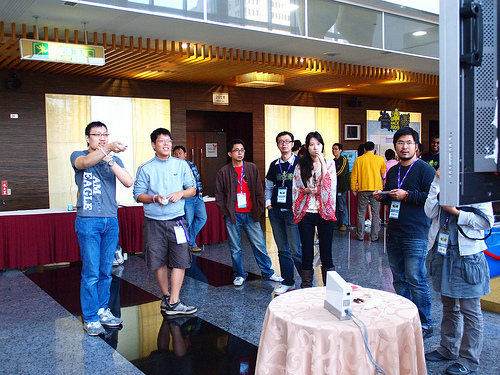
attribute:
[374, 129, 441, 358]
person — wearing lanyard, watching wii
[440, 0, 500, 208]
tv — here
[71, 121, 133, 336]
man — smiling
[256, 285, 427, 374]
table — round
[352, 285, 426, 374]
tablecloth — pink, cotton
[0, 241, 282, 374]
floor — marble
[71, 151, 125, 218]
shirt — blue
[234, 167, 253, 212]
shirt — red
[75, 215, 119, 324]
jeans — medium blue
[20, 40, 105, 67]
sign — hanging